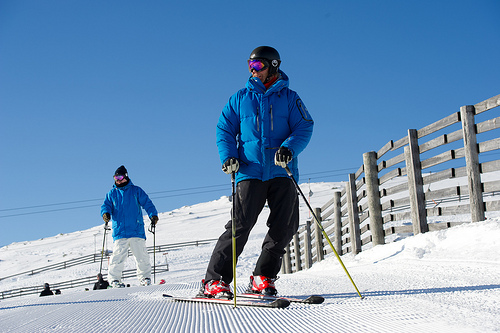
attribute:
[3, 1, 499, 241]
sky — blue, clear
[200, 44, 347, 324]
person — skiing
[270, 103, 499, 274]
fence — wooden, long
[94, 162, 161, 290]
person — skiing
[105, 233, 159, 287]
pants — white, baggy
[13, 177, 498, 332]
snow — white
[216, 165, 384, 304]
ski poles — long, metal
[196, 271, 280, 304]
ski boots — red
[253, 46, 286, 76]
helmet — black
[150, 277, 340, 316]
skis — long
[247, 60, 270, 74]
goggles — purple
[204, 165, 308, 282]
pants — black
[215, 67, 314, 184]
coat — blue, fluffy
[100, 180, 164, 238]
jacket — blue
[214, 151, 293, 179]
gloves — black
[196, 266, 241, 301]
left ski boot — red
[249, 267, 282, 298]
right ski boot — red